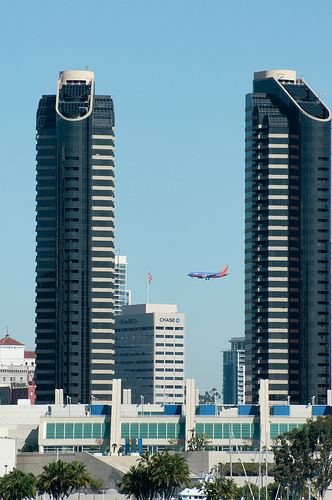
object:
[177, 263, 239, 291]
plane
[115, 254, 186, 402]
buildings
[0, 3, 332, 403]
sky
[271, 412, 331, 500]
trees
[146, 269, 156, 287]
flag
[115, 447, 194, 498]
trees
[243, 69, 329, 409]
building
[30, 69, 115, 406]
building